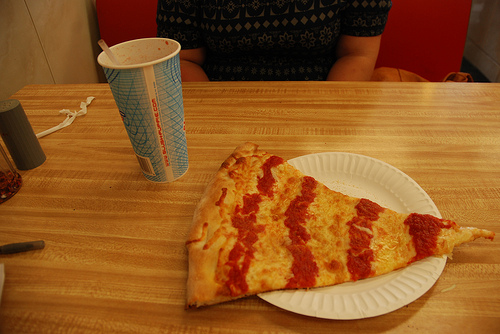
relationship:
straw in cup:
[97, 37, 122, 66] [97, 38, 188, 180]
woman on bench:
[156, 1, 388, 81] [97, 1, 473, 77]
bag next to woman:
[378, 66, 471, 82] [156, 1, 388, 81]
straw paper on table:
[36, 98, 94, 137] [1, 83, 498, 334]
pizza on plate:
[183, 141, 495, 312] [260, 153, 445, 322]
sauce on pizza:
[405, 214, 444, 254] [183, 141, 495, 312]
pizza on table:
[183, 141, 495, 312] [1, 83, 498, 334]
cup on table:
[97, 38, 188, 180] [1, 83, 498, 334]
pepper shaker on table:
[0, 100, 45, 169] [1, 83, 498, 334]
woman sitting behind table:
[156, 1, 388, 81] [1, 83, 498, 334]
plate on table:
[260, 153, 445, 322] [1, 83, 498, 334]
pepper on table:
[0, 146, 21, 208] [1, 83, 498, 334]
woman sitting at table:
[156, 1, 388, 81] [1, 83, 498, 334]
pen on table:
[0, 242, 44, 257] [1, 83, 498, 334]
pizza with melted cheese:
[183, 141, 495, 312] [373, 211, 412, 267]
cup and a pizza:
[97, 38, 188, 180] [183, 141, 495, 312]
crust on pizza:
[188, 144, 248, 306] [183, 141, 495, 312]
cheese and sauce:
[373, 211, 412, 267] [405, 214, 444, 254]